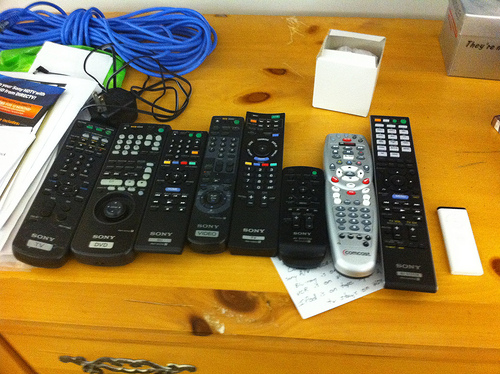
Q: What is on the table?
A: Remotes.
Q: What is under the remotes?
A: A paper.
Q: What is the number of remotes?
A: Eight.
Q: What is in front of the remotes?
A: A box.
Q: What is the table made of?
A: Wood.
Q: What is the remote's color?
A: Black and silver.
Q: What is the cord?
A: Power cord.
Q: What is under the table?
A: Drawers.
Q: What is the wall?
A: White.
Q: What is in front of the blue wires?
A: Remotes.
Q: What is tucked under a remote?
A: A note.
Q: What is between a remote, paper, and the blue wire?
A: A black plug?.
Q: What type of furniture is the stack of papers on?
A: A dresser.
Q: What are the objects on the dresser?
A: Remote controls.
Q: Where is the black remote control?
A: On a dresser.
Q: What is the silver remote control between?
A: Two black remote controls.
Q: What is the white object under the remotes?
A: Paper.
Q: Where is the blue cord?
A: On the table.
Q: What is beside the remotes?
A: Papers.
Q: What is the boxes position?
A: Opened.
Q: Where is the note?
A: Under the remotes.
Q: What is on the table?
A: A box.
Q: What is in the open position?
A: A box.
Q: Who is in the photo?
A: No one.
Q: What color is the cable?
A: Blue.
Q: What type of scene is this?
A: Indoor.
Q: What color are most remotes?
A: Black.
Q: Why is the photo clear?
A: Room is well lit.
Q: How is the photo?
A: Clear.